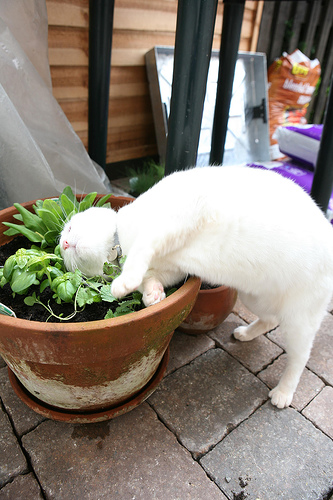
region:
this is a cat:
[59, 143, 323, 412]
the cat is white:
[55, 148, 330, 421]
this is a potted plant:
[2, 193, 212, 447]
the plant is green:
[0, 190, 144, 309]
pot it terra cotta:
[4, 198, 218, 453]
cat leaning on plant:
[8, 174, 331, 430]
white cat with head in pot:
[52, 161, 331, 418]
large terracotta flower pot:
[0, 190, 207, 429]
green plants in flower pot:
[1, 183, 184, 331]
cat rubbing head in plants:
[53, 162, 330, 419]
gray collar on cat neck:
[105, 220, 125, 267]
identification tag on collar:
[104, 243, 119, 262]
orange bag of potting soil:
[258, 47, 326, 163]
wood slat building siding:
[1, 0, 270, 170]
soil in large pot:
[1, 228, 191, 324]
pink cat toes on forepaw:
[144, 281, 168, 305]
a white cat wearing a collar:
[91, 142, 326, 354]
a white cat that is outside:
[52, 177, 319, 425]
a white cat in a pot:
[14, 138, 314, 354]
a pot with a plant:
[23, 172, 175, 433]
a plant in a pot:
[2, 184, 223, 452]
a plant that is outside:
[28, 163, 213, 436]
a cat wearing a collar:
[69, 172, 319, 319]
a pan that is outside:
[140, 34, 285, 171]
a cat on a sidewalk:
[41, 153, 331, 478]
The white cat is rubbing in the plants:
[41, 115, 331, 427]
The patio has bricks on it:
[156, 374, 304, 490]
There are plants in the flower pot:
[10, 187, 170, 333]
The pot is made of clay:
[3, 181, 212, 437]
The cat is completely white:
[65, 143, 322, 420]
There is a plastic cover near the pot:
[2, 6, 134, 236]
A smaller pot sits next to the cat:
[126, 148, 258, 359]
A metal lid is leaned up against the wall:
[127, 36, 291, 177]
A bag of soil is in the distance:
[262, 36, 320, 175]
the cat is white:
[51, 170, 317, 391]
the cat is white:
[51, 173, 322, 425]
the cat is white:
[39, 152, 317, 431]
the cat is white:
[46, 154, 313, 416]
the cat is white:
[54, 157, 330, 411]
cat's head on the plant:
[30, 182, 161, 319]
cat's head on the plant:
[23, 192, 143, 294]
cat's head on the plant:
[19, 188, 147, 319]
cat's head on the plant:
[23, 188, 129, 292]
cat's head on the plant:
[34, 191, 140, 286]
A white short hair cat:
[16, 128, 331, 378]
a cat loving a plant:
[15, 160, 303, 390]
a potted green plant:
[4, 176, 229, 438]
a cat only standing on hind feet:
[52, 121, 323, 421]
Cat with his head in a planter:
[41, 164, 331, 408]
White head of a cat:
[58, 202, 119, 277]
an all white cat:
[55, 160, 332, 406]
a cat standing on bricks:
[64, 163, 331, 409]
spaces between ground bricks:
[172, 422, 220, 484]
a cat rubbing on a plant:
[2, 163, 332, 423]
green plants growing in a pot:
[1, 192, 201, 420]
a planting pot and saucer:
[1, 194, 199, 428]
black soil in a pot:
[14, 288, 95, 323]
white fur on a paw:
[269, 383, 295, 408]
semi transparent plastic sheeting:
[0, 2, 110, 198]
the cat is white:
[59, 165, 331, 410]